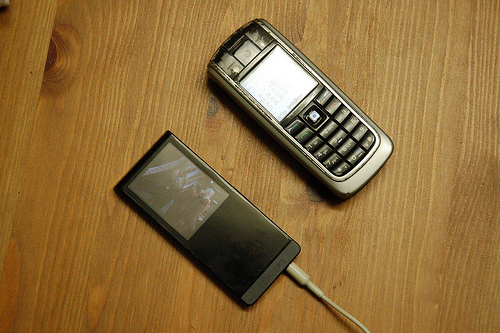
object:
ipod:
[111, 129, 301, 310]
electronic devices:
[206, 18, 396, 198]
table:
[3, 0, 500, 332]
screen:
[126, 136, 232, 240]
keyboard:
[283, 87, 379, 177]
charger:
[285, 259, 371, 333]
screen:
[237, 41, 320, 122]